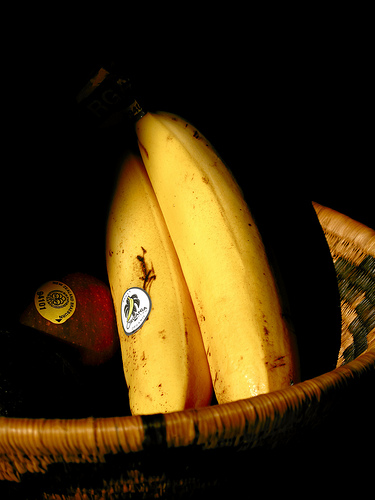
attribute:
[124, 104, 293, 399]
banana — yellow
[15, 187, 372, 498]
basket — brown, green, wicker, straw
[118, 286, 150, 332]
sticker — white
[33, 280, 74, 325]
sticker — yellow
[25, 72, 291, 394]
fruit — grouped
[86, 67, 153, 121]
stem — brown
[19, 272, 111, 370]
apple — red, hidden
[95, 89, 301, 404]
bananas — pair, bundled, yellow, ripe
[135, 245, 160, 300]
spots — brown